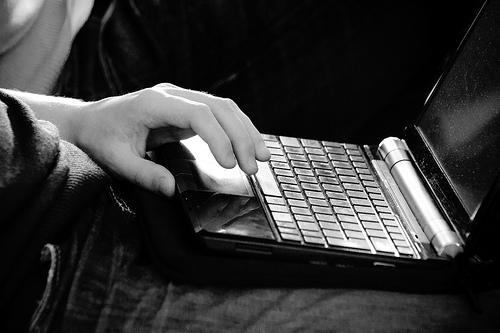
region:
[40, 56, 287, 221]
hand hovering above laptop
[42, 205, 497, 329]
black pant leg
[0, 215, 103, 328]
pocket of pants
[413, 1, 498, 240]
dusty black laptop screen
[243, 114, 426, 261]
keyboard of a laptop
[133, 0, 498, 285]
black plastic laptop on a lap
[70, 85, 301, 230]
hand touching a laptop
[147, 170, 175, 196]
thumb of a hand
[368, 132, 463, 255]
grey hinge of a laptop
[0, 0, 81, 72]
white cloth in background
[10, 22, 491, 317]
black and white photo of a man and laptop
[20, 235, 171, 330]
man's blue jeans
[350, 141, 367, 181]
F keys on a keyboard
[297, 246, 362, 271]
auxillery ports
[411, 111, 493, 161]
portion of a compter screen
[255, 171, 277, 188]
part of the space bar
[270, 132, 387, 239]
keyboard of a laptop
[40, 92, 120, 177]
wrist resting on stomach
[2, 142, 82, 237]
man's sweater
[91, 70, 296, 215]
fingers about to touch keys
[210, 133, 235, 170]
part of a finger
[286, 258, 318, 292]
edge of a latop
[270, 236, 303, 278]
part of a laptop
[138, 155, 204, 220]
part of a finger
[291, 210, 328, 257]
part of a button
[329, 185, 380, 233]
part of a laptop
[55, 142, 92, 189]
part of a sweater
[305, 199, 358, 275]
part of a laptop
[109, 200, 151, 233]
part of a long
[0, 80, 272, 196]
the left hand of a man's hand above the laptop's keyboard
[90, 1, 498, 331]
a laptop computer on the boy's lap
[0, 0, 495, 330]
the lap of a young boy holding a laptop computer and a cover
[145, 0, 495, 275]
a laptop computer on a cover on the young man's lap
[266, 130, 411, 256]
the keys on the keyboard of a laptop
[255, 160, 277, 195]
part of a space bar on a keyboard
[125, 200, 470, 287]
a laptop computer cover on the boy's lap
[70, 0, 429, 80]
a bag to carry the laptop computer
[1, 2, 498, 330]
a person wearing denim jeans holding a laptop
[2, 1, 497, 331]
a young person sitting down using a laptop computer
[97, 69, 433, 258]
hand typing on keyboard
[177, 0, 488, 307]
black laptop with shinny keyboards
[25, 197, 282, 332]
men's dark denim pants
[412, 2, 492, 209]
laptop screen is off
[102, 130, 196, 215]
thumb touching black laptop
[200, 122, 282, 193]
nicely trims male nails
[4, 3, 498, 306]
black and white photo of a man using a laptop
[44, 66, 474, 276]
left hand on laptop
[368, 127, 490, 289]
round corner on laptop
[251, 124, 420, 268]
silver keys on a laptop